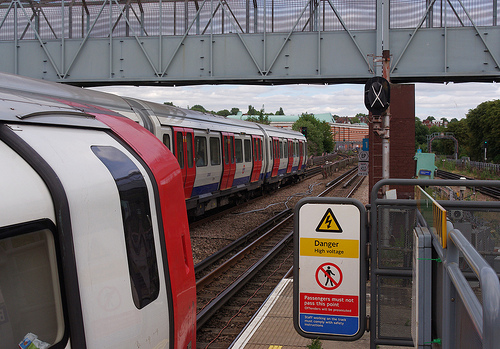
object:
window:
[0, 219, 67, 349]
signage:
[298, 203, 361, 337]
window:
[85, 145, 160, 310]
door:
[271, 137, 281, 177]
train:
[0, 72, 309, 219]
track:
[180, 165, 369, 346]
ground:
[194, 268, 366, 349]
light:
[484, 140, 488, 147]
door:
[171, 125, 197, 200]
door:
[250, 134, 263, 183]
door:
[287, 138, 293, 173]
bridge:
[0, 0, 500, 88]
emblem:
[292, 197, 367, 343]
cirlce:
[315, 262, 344, 291]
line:
[320, 267, 338, 286]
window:
[163, 131, 308, 170]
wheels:
[189, 174, 299, 248]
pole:
[369, 82, 417, 349]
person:
[195, 150, 204, 167]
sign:
[362, 138, 370, 152]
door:
[219, 132, 237, 191]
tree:
[290, 111, 338, 164]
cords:
[232, 177, 323, 219]